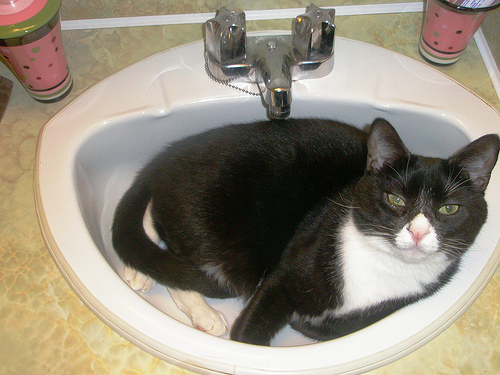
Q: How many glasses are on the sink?
A: Two.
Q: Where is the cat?
A: In the sink.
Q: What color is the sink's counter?
A: Beige.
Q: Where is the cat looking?
A: At the camera.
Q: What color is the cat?
A: Black and white.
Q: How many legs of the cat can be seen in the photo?
A: Three.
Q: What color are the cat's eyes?
A: Green.